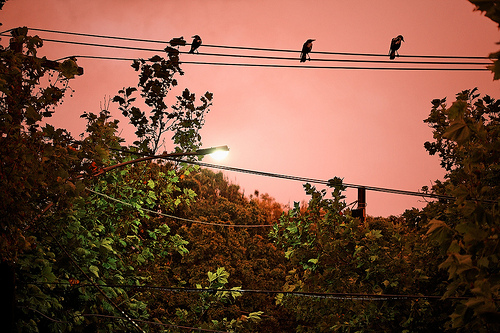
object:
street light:
[101, 144, 229, 171]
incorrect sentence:
[209, 65, 434, 197]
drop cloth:
[298, 38, 318, 63]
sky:
[0, 0, 499, 217]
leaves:
[319, 192, 333, 204]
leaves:
[194, 268, 245, 307]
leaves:
[110, 85, 138, 112]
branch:
[80, 147, 225, 178]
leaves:
[161, 69, 188, 90]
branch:
[116, 91, 150, 143]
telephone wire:
[2, 275, 478, 304]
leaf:
[365, 231, 385, 241]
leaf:
[339, 219, 348, 227]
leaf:
[285, 222, 300, 232]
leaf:
[286, 247, 296, 256]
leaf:
[309, 257, 322, 263]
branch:
[275, 232, 333, 304]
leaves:
[35, 85, 60, 98]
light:
[187, 145, 240, 167]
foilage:
[196, 258, 246, 301]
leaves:
[167, 113, 207, 134]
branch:
[51, 188, 123, 265]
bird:
[188, 33, 203, 56]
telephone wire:
[3, 27, 496, 74]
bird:
[388, 33, 405, 60]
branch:
[154, 118, 171, 147]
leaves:
[177, 86, 214, 115]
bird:
[298, 38, 317, 64]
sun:
[206, 142, 235, 165]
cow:
[225, 142, 303, 183]